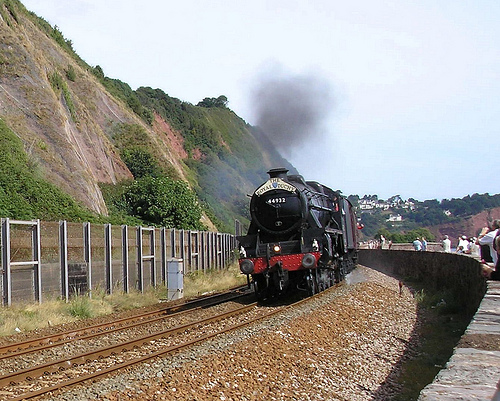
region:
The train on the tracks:
[230, 159, 362, 306]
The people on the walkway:
[367, 218, 499, 286]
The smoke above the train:
[200, 58, 339, 248]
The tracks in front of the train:
[0, 293, 290, 399]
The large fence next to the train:
[1, 211, 246, 310]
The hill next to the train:
[0, 1, 306, 308]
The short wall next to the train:
[357, 246, 497, 398]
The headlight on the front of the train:
[271, 243, 281, 255]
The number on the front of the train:
[263, 195, 289, 205]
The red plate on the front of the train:
[233, 248, 323, 278]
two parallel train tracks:
[37, 319, 114, 386]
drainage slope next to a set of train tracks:
[255, 326, 360, 397]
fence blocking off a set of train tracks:
[20, 204, 135, 300]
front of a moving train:
[245, 194, 304, 281]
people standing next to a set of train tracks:
[399, 235, 479, 264]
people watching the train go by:
[364, 219, 494, 269]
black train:
[227, 167, 334, 292]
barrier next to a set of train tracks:
[386, 245, 496, 270]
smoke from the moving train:
[263, 79, 313, 164]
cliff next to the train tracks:
[28, 57, 153, 159]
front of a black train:
[232, 143, 370, 313]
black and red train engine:
[232, 164, 361, 306]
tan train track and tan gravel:
[120, 303, 332, 385]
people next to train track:
[371, 230, 498, 245]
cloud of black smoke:
[231, 48, 336, 173]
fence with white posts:
[30, 212, 234, 298]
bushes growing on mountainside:
[32, 64, 194, 218]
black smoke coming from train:
[227, 79, 356, 296]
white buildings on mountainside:
[357, 183, 411, 230]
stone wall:
[419, 237, 494, 399]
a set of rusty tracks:
[2, 262, 391, 395]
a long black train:
[224, 157, 377, 318]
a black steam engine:
[220, 153, 372, 330]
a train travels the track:
[213, 136, 373, 318]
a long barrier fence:
[9, 202, 266, 312]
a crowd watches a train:
[197, 142, 489, 324]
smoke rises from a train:
[181, 52, 396, 328]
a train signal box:
[138, 237, 208, 313]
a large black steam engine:
[193, 50, 390, 320]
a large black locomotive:
[198, 141, 391, 323]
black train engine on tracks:
[219, 86, 376, 305]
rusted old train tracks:
[56, 302, 238, 392]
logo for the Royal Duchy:
[247, 165, 302, 212]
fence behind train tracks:
[5, 213, 187, 300]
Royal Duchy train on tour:
[192, 123, 379, 353]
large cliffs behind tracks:
[18, 14, 225, 226]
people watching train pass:
[395, 220, 498, 270]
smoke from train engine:
[238, 78, 331, 182]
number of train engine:
[253, 188, 302, 227]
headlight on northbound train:
[241, 233, 308, 268]